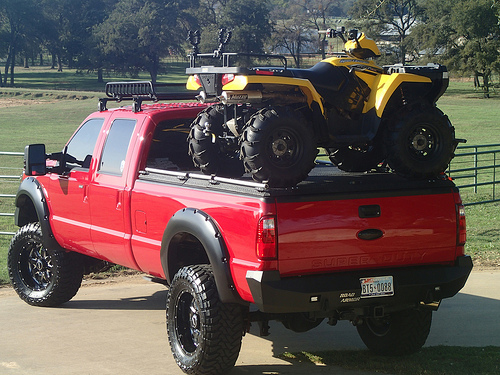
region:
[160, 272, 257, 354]
A wheel on the truck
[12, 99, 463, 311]
A red truck in the photo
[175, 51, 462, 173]
A bike on the truck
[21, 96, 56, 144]
Grass in the photo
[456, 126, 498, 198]
A fence in the photo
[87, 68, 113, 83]
A tree trunk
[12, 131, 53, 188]
A side mirror on the truck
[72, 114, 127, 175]
Window on the truck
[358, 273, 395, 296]
The license plate on a truck.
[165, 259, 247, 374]
A tire on a truck.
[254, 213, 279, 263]
A tail light on a truck.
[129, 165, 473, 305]
The bed of a truck.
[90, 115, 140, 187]
The window on a truck.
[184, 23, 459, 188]
A yellow ATV on the truck.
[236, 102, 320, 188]
Tire on a ATV.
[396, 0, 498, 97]
A green growing tree.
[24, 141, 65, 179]
A side mirror on a truck.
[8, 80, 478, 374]
red truck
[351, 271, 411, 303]
Texas license plate on the back of the truck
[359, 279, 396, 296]
black writing on the license plate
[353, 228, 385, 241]
black handle on the back of the truck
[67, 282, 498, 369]
shadows on the ground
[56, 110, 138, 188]
two windows on the side of the truck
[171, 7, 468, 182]
yellow and black ATV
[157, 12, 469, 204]
vehicle on the back of the truck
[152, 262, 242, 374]
large black wheel on the back of the truck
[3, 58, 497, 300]
green grass on the ground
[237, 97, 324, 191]
black tire on an atv vehicle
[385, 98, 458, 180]
black tire on an atv vehicle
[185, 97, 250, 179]
black tire on an atv vehicle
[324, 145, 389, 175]
black tire on an atv vehicle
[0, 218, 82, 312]
black tire on a red truck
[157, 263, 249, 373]
black tire on a red truck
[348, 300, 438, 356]
black tire on a red truck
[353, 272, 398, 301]
license plate on a red truck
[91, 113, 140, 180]
window on a red truck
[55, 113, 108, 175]
window on a red truck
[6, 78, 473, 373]
the parked red truck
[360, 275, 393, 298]
the license plate on the truck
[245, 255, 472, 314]
the bumper on the back of the truck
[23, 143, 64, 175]
the side view mirror on the truck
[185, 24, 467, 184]
the ATV on the back of the truck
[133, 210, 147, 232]
the cover to the gas tank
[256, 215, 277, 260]
the light on the back of the truck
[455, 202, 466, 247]
the light on the back of the truck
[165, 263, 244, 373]
the wheel on the back of the truck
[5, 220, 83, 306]
the wheel on the front of the truck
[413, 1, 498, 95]
a tree in a field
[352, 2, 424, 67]
a tree in a field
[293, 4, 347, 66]
a tree in a field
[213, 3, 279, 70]
a tree in a field